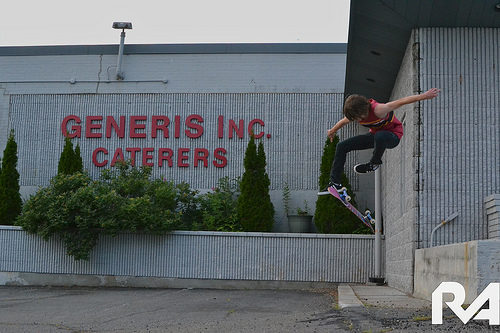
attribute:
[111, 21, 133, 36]
camera — white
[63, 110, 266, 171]
letters — red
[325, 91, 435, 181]
guy — skateboarding, airborne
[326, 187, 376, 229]
skateboard — pink, airborne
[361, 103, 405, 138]
shirt — red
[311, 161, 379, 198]
shoes — black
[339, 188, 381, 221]
wheels — white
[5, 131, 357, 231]
trees — green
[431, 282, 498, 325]
ra — white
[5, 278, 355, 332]
pavement — grey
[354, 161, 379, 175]
shoe — black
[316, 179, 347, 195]
shoe — black